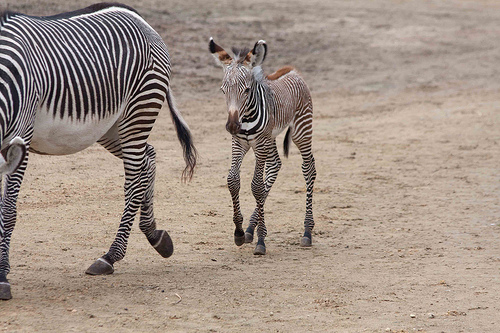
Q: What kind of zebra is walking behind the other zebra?
A: A child zebra.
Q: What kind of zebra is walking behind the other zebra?
A: A baby zebra.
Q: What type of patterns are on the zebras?
A: Stripes.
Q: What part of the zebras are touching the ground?
A: The hooves.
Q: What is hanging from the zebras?
A: Their tails.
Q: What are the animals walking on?
A: Dirt.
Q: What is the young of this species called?
A: Foal.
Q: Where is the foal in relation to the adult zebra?
A: Behind it.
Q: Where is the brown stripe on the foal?
A: Middle of back.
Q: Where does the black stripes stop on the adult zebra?
A: Stomach.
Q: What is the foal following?
A: Mother.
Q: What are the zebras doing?
A: Walking.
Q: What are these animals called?
A: Zebras.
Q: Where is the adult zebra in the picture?
A: Left foreground.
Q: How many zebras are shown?
A: 2.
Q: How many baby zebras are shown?
A: 1.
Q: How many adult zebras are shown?
A: 1.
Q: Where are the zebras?
A: On dirt.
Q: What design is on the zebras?
A: Stripes.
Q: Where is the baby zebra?
A: Behind the adult.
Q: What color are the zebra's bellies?
A: White.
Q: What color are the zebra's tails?
A: Black.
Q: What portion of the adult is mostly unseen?
A: Head.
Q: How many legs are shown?
A: 7.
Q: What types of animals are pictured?
A: Zebras.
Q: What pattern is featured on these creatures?
A: Stripes.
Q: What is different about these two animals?
A: One is adult, the other is young.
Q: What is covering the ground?
A: Dirt.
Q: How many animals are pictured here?
A: Two.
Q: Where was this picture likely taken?
A: Africa.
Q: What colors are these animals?
A: Black and white.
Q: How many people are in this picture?
A: Zero.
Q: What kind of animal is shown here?
A: Zebra.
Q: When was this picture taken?
A: Daytime.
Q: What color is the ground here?
A: Brown.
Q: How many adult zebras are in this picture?
A: One.